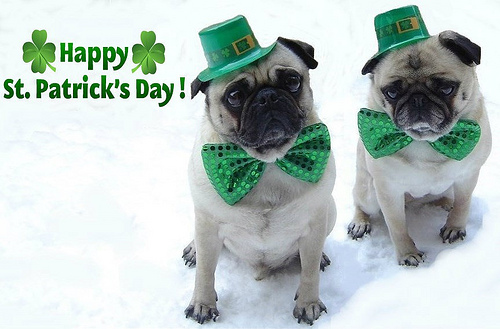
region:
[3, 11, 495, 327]
St. Patrick's Day advertisements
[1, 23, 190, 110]
St. Patrick's Day logo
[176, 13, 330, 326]
one dog in a Irish hat and bowtie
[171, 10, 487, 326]
2 dogs in a hat and bowtie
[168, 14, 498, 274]
the dogs are white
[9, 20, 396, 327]
the background is white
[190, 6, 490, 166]
the dogs look uninterested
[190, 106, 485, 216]
the green bowties have dots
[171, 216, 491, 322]
the dogs paws have sharp nails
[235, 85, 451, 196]
the pug faces might be cute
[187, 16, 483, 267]
two dogs wearing hats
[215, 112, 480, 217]
two green bowties in photo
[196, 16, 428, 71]
two green hats in photo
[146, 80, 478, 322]
two dogs sitting in snow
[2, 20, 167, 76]
two four leaf clovers in photo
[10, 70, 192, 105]
green writing says happy st patricks day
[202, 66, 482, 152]
two beige dogs with black snouts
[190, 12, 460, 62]
two hats with gold buckles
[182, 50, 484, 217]
two dogs wearing green bowties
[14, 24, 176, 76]
the word happy in between four leaf clovers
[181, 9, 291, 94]
a green top hat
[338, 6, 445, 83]
a green top hat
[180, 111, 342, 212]
a green bow tie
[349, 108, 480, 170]
a bow tie with sequins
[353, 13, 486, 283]
a pug dressed up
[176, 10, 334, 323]
a pug dressed up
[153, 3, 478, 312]
two pugs dressed up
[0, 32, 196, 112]
slogan for a picture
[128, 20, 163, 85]
a four leaf clover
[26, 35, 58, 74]
a four leaf clover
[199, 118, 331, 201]
a green bow tie on a dog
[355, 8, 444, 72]
a green hat on a dog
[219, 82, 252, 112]
a black eye on a dog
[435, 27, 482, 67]
a black ear on a dog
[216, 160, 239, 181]
green sequins on a bow tie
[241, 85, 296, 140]
a black snout on a pug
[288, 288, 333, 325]
black claws on a dog's paw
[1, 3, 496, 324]
a white background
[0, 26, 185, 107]
green words next to two dogs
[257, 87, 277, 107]
a black nose on a dog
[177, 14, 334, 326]
a black and white pug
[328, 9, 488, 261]
a black and white pug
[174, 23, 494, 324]
two dogs standing next to each other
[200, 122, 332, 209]
a shiny green bow tie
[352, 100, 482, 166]
a shiny green bow tie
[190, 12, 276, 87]
a plastic green clover hat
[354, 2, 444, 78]
a plastic green clover hat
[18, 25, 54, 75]
a green clover graphic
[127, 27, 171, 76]
a green clover graphic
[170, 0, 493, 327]
dogs dressed up for St. Patrick's Day